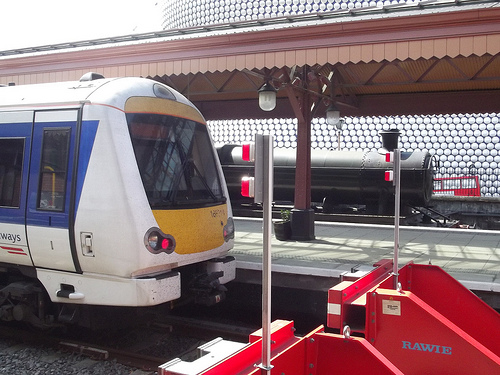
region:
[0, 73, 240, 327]
a white and blue train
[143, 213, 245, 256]
a train's head lights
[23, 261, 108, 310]
a black and white step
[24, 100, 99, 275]
a blue and white door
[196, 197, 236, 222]
the train number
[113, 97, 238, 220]
a very large windshield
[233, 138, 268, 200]
two round, red lights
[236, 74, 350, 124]
two quaint light fixtures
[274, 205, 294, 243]
a small potted plant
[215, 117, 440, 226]
a part of a train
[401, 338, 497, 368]
The word RAWIE written in blue.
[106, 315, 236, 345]
Tracks for the vehicle to drive on.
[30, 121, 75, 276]
Door of the vehicle.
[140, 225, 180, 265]
Lights on the vehicle.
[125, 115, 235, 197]
The windshield of the vehicle.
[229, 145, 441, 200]
A round train car on the opposite side of the tracks.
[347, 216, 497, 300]
The platform in between the tracks.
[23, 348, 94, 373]
Gravel next to the tracks.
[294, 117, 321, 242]
A beam holding the roof up.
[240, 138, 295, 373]
Metal pole with red lights.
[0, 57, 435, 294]
Two trains at station.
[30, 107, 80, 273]
A blue and white train door.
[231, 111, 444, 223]
An old black train engine.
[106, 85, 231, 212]
Large train windshield.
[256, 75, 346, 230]
Two lights on a light pole.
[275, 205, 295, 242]
A flowerpot by a light pole.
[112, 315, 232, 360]
Train tracks on gravel.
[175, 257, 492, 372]
Two red items to help stop train.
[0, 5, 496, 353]
An outside train station.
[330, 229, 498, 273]
Gray concrete walk way.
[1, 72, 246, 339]
a railway car at the station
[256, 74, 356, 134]
a set of lights on a beam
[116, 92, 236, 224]
the front window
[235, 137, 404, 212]
two sets of red lights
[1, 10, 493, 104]
a covered area at the station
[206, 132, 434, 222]
a black train car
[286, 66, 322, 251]
a tall metal beam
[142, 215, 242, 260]
a pair of headlights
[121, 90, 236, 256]
yellow portion of a train car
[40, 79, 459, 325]
Two trains are seen.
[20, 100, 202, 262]
Train is yellow, white and blue color.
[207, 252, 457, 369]
Stopper is red color.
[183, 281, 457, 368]
Two stopper are seen.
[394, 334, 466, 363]
Rawie is written in the stopper.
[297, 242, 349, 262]
pathway is grey color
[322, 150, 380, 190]
Engine is black in color.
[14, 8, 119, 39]
Sky is white color.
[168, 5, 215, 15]
Building is grey color.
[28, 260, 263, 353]
Train is on track.